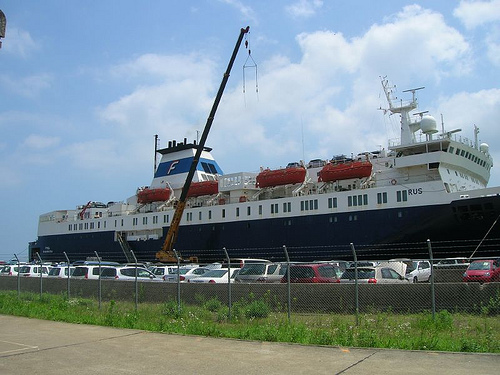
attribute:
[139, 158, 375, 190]
rafts — red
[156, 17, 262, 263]
crane — metal, small, black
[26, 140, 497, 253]
ship — blue, white, windowed, present, lined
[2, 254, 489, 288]
cars — parked, rowed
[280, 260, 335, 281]
car — red, gold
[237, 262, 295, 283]
car — gold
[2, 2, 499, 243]
sky — blue, white, cloudy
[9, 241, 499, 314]
fence — metal, wire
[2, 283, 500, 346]
grass — green, tall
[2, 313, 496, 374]
ground — gray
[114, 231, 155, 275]
stairs — leading up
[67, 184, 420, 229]
windows — rowed